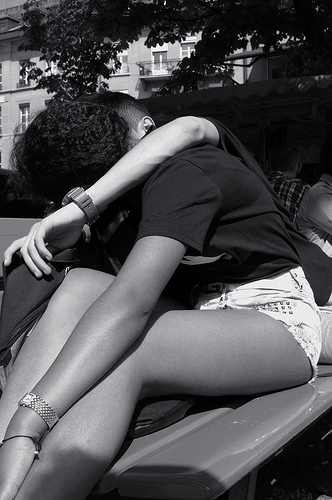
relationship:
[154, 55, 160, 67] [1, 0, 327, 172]
window in building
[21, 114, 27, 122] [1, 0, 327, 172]
window in building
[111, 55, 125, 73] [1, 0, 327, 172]
window in building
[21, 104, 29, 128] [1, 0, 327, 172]
window in building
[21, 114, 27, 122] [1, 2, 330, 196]
window on building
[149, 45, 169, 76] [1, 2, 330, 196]
window on building